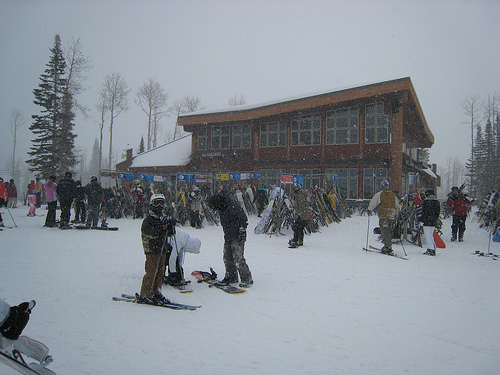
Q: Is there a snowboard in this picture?
A: Yes, there is a snowboard.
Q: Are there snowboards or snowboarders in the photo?
A: Yes, there is a snowboard.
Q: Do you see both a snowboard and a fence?
A: No, there is a snowboard but no fences.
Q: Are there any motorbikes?
A: No, there are no motorbikes.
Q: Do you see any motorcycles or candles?
A: No, there are no motorcycles or candles.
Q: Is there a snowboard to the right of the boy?
A: Yes, there is a snowboard to the right of the boy.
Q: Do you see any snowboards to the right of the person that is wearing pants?
A: Yes, there is a snowboard to the right of the boy.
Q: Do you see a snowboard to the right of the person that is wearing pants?
A: Yes, there is a snowboard to the right of the boy.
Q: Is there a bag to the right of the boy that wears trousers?
A: No, there is a snowboard to the right of the boy.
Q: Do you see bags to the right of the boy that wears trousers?
A: No, there is a snowboard to the right of the boy.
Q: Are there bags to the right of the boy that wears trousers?
A: No, there is a snowboard to the right of the boy.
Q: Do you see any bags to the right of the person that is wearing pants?
A: No, there is a snowboard to the right of the boy.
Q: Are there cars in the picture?
A: No, there are no cars.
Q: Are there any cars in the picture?
A: No, there are no cars.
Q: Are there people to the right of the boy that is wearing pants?
A: Yes, there is a person to the right of the boy.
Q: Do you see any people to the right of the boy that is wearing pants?
A: Yes, there is a person to the right of the boy.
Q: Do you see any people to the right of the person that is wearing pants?
A: Yes, there is a person to the right of the boy.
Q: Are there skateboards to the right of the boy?
A: No, there is a person to the right of the boy.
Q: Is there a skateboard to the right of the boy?
A: No, there is a person to the right of the boy.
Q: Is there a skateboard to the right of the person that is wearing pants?
A: No, there is a person to the right of the boy.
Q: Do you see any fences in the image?
A: No, there are no fences.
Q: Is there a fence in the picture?
A: No, there are no fences.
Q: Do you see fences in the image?
A: No, there are no fences.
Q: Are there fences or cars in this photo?
A: No, there are no fences or cars.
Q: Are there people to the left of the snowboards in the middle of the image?
A: Yes, there is a person to the left of the snowboards.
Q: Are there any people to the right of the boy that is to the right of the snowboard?
A: Yes, there is a person to the right of the boy.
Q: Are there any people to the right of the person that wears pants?
A: Yes, there is a person to the right of the boy.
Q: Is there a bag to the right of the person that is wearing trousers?
A: No, there is a person to the right of the boy.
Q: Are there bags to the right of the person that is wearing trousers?
A: No, there is a person to the right of the boy.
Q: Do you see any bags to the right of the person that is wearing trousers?
A: No, there is a person to the right of the boy.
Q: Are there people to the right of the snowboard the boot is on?
A: Yes, there is a person to the right of the snow board.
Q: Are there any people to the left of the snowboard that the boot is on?
A: No, the person is to the right of the snowboard.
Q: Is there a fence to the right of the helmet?
A: No, there is a person to the right of the helmet.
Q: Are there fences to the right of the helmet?
A: No, there is a person to the right of the helmet.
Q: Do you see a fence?
A: No, there are no fences.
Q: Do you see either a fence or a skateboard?
A: No, there are no fences or skateboards.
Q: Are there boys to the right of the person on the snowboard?
A: Yes, there is a boy to the right of the person.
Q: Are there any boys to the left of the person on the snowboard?
A: No, the boy is to the right of the person.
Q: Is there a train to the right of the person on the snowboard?
A: No, there is a boy to the right of the person.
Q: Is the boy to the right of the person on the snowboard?
A: Yes, the boy is to the right of the person.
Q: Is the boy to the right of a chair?
A: No, the boy is to the right of the person.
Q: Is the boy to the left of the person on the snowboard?
A: No, the boy is to the right of the person.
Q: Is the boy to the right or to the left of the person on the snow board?
A: The boy is to the right of the person.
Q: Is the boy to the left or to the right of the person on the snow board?
A: The boy is to the right of the person.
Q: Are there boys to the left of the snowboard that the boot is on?
A: Yes, there is a boy to the left of the snowboard.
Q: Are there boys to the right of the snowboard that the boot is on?
A: No, the boy is to the left of the snow board.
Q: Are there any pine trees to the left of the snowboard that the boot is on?
A: No, there is a boy to the left of the snow board.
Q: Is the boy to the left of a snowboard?
A: Yes, the boy is to the left of a snowboard.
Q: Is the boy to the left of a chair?
A: No, the boy is to the left of a snowboard.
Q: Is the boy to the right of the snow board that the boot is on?
A: No, the boy is to the left of the snowboard.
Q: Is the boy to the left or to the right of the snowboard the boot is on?
A: The boy is to the left of the snowboard.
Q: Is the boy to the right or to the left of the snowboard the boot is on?
A: The boy is to the left of the snowboard.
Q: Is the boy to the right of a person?
A: Yes, the boy is to the right of a person.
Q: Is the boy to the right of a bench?
A: No, the boy is to the right of a person.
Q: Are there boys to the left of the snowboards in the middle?
A: Yes, there is a boy to the left of the snowboards.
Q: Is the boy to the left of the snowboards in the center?
A: Yes, the boy is to the left of the snowboards.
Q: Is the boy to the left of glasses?
A: No, the boy is to the left of the snowboards.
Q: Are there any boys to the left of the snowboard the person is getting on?
A: Yes, there is a boy to the left of the snow board.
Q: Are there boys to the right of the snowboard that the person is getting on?
A: No, the boy is to the left of the snowboard.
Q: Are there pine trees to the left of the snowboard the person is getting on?
A: No, there is a boy to the left of the snowboard.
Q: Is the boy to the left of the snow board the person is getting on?
A: Yes, the boy is to the left of the snowboard.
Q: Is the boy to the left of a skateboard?
A: No, the boy is to the left of the snowboard.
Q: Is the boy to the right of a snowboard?
A: No, the boy is to the left of a snowboard.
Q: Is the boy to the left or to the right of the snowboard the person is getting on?
A: The boy is to the left of the snowboard.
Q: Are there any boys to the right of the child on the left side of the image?
A: Yes, there is a boy to the right of the child.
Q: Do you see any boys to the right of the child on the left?
A: Yes, there is a boy to the right of the child.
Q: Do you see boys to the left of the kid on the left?
A: No, the boy is to the right of the child.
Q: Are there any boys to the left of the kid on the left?
A: No, the boy is to the right of the child.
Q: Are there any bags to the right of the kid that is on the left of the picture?
A: No, there is a boy to the right of the kid.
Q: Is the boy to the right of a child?
A: Yes, the boy is to the right of a child.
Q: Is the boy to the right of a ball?
A: No, the boy is to the right of a child.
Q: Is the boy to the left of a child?
A: No, the boy is to the right of a child.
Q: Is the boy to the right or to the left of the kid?
A: The boy is to the right of the kid.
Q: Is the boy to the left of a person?
A: Yes, the boy is to the left of a person.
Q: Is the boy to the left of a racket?
A: No, the boy is to the left of a person.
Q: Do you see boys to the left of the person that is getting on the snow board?
A: Yes, there is a boy to the left of the person.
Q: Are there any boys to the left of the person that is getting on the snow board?
A: Yes, there is a boy to the left of the person.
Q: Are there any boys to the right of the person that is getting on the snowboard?
A: No, the boy is to the left of the person.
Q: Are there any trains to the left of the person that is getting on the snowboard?
A: No, there is a boy to the left of the person.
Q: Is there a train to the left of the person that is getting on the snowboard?
A: No, there is a boy to the left of the person.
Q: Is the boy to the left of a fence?
A: No, the boy is to the left of a person.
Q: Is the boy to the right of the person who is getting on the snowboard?
A: No, the boy is to the left of the person.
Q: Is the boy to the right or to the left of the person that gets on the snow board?
A: The boy is to the left of the person.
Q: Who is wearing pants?
A: The boy is wearing pants.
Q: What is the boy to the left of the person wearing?
A: The boy is wearing pants.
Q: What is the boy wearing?
A: The boy is wearing pants.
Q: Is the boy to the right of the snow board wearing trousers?
A: Yes, the boy is wearing trousers.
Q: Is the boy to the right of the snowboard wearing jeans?
A: No, the boy is wearing trousers.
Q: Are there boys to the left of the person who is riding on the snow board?
A: Yes, there is a boy to the left of the person.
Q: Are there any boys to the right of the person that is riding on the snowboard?
A: No, the boy is to the left of the person.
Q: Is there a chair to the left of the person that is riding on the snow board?
A: No, there is a boy to the left of the person.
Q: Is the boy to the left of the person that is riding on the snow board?
A: Yes, the boy is to the left of the person.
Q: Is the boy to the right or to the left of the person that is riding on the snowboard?
A: The boy is to the left of the person.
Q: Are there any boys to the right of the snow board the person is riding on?
A: Yes, there is a boy to the right of the snowboard.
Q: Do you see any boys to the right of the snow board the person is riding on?
A: Yes, there is a boy to the right of the snowboard.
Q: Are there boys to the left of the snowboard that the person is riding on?
A: No, the boy is to the right of the snowboard.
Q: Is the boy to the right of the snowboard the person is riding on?
A: Yes, the boy is to the right of the snowboard.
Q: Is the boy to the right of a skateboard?
A: No, the boy is to the right of the snowboard.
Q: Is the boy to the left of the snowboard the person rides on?
A: No, the boy is to the right of the snowboard.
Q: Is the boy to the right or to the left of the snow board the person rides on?
A: The boy is to the right of the snowboard.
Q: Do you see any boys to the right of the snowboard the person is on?
A: Yes, there is a boy to the right of the snowboard.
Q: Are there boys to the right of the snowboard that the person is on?
A: Yes, there is a boy to the right of the snowboard.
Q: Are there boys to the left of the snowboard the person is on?
A: No, the boy is to the right of the snow board.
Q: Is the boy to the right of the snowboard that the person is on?
A: Yes, the boy is to the right of the snowboard.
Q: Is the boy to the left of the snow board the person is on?
A: No, the boy is to the right of the snowboard.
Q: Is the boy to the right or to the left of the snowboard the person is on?
A: The boy is to the right of the snowboard.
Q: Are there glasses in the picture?
A: No, there are no glasses.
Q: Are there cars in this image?
A: No, there are no cars.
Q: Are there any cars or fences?
A: No, there are no cars or fences.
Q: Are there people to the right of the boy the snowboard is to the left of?
A: Yes, there are people to the right of the boy.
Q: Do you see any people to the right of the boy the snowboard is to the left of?
A: Yes, there are people to the right of the boy.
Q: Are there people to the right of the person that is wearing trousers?
A: Yes, there are people to the right of the boy.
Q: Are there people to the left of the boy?
A: No, the people are to the right of the boy.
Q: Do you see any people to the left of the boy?
A: No, the people are to the right of the boy.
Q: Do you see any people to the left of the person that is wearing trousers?
A: No, the people are to the right of the boy.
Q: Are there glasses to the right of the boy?
A: No, there are people to the right of the boy.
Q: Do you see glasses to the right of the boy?
A: No, there are people to the right of the boy.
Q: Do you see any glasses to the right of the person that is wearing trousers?
A: No, there are people to the right of the boy.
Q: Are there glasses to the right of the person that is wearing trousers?
A: No, there are people to the right of the boy.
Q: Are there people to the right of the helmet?
A: Yes, there are people to the right of the helmet.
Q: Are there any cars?
A: No, there are no cars.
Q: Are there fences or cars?
A: No, there are no cars or fences.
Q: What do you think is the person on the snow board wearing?
A: The person is wearing a jacket.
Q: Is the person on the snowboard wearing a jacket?
A: Yes, the person is wearing a jacket.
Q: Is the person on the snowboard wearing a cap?
A: No, the person is wearing a jacket.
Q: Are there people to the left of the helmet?
A: Yes, there is a person to the left of the helmet.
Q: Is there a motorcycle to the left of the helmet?
A: No, there is a person to the left of the helmet.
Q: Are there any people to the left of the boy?
A: Yes, there is a person to the left of the boy.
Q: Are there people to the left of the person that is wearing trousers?
A: Yes, there is a person to the left of the boy.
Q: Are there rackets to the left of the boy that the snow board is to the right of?
A: No, there is a person to the left of the boy.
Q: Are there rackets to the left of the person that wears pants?
A: No, there is a person to the left of the boy.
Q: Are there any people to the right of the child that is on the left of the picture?
A: Yes, there is a person to the right of the child.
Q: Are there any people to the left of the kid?
A: No, the person is to the right of the kid.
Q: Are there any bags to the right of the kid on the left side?
A: No, there is a person to the right of the child.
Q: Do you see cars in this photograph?
A: No, there are no cars.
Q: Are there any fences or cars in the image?
A: No, there are no cars or fences.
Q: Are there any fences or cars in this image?
A: No, there are no cars or fences.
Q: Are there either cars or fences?
A: No, there are no cars or fences.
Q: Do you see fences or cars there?
A: No, there are no cars or fences.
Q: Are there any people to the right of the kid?
A: Yes, there is a person to the right of the kid.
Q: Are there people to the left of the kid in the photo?
A: No, the person is to the right of the kid.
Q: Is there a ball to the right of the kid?
A: No, there is a person to the right of the kid.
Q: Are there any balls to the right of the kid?
A: No, there is a person to the right of the kid.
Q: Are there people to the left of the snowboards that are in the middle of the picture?
A: Yes, there is a person to the left of the snowboards.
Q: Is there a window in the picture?
A: Yes, there are windows.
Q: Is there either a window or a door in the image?
A: Yes, there are windows.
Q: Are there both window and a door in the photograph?
A: No, there are windows but no doors.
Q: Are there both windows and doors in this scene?
A: No, there are windows but no doors.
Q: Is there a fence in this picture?
A: No, there are no fences.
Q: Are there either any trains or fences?
A: No, there are no fences or trains.